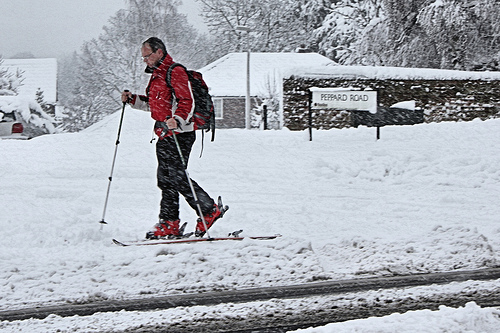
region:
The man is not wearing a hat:
[88, 16, 305, 263]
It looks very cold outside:
[46, 18, 397, 279]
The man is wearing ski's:
[84, 182, 304, 261]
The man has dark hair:
[101, 23, 186, 73]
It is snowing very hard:
[27, 20, 312, 286]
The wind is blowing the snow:
[73, 18, 311, 264]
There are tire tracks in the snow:
[252, 241, 492, 328]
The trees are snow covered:
[214, 2, 496, 99]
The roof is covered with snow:
[189, 40, 444, 160]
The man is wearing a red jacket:
[112, 53, 257, 168]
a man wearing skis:
[73, 8, 228, 268]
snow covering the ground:
[290, 131, 458, 258]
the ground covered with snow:
[231, 107, 463, 252]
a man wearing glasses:
[136, 41, 171, 71]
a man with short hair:
[137, 30, 172, 76]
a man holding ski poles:
[93, 41, 194, 238]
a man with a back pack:
[176, 48, 214, 139]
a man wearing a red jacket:
[138, 41, 186, 148]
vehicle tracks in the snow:
[161, 255, 465, 332]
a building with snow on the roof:
[229, 38, 333, 118]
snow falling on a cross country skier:
[2, 5, 496, 330]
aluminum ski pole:
[98, 89, 130, 228]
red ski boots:
[147, 202, 224, 239]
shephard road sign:
[310, 86, 377, 139]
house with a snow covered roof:
[193, 48, 343, 128]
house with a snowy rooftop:
[1, 56, 60, 141]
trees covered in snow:
[56, 1, 498, 126]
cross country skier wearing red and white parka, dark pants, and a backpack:
[100, 36, 285, 251]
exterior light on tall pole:
[235, 21, 257, 131]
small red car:
[10, 121, 23, 133]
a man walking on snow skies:
[96, 30, 290, 257]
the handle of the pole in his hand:
[116, 86, 136, 104]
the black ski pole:
[91, 106, 130, 238]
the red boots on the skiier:
[143, 203, 225, 244]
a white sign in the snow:
[303, 86, 376, 121]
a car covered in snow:
[0, 94, 48, 146]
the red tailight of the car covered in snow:
[10, 118, 25, 135]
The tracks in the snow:
[87, 264, 493, 329]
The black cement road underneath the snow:
[153, 290, 385, 331]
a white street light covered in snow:
[227, 21, 259, 136]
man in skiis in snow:
[101, 24, 267, 263]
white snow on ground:
[281, 164, 440, 218]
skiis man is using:
[96, 231, 299, 252]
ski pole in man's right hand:
[99, 90, 129, 235]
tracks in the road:
[248, 268, 480, 329]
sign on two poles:
[298, 77, 390, 143]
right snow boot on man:
[139, 212, 184, 238]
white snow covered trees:
[288, 3, 485, 66]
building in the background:
[4, 36, 62, 106]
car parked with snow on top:
[2, 86, 57, 157]